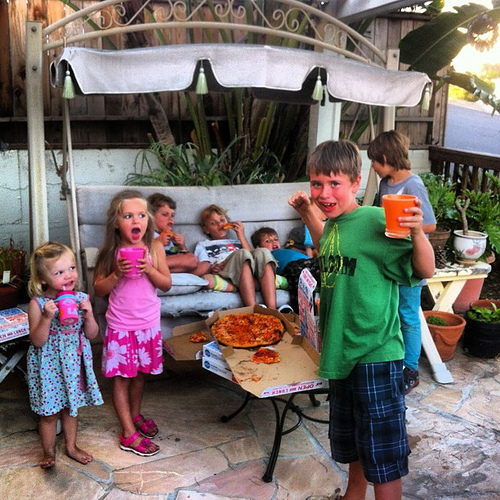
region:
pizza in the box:
[198, 299, 305, 370]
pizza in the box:
[212, 301, 331, 385]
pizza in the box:
[218, 279, 305, 365]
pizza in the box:
[198, 312, 340, 384]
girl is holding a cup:
[94, 180, 189, 395]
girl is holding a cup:
[19, 227, 90, 366]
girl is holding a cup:
[109, 195, 194, 334]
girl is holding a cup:
[19, 233, 131, 405]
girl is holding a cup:
[84, 155, 199, 322]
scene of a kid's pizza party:
[0, 3, 485, 483]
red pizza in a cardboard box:
[202, 308, 326, 402]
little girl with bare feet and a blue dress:
[20, 238, 100, 473]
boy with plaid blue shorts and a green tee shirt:
[283, 135, 439, 494]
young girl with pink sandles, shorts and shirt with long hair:
[89, 187, 174, 457]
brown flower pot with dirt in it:
[417, 306, 466, 361]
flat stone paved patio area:
[1, 355, 485, 492]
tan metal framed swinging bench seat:
[17, 0, 459, 399]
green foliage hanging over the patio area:
[395, 0, 490, 122]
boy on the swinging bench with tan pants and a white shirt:
[190, 204, 297, 319]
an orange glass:
[382, 192, 419, 239]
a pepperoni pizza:
[212, 311, 284, 348]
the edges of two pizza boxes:
[200, 340, 237, 385]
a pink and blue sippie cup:
[49, 289, 83, 322]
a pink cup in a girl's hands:
[120, 245, 146, 277]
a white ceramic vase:
[455, 226, 485, 259]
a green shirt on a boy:
[317, 207, 424, 379]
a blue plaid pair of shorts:
[327, 354, 412, 483]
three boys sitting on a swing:
[147, 191, 313, 308]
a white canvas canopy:
[57, 43, 434, 110]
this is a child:
[20, 242, 101, 477]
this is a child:
[92, 165, 178, 472]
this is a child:
[150, 186, 206, 308]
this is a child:
[179, 195, 290, 342]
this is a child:
[249, 223, 319, 335]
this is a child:
[277, 141, 424, 493]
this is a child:
[364, 127, 456, 426]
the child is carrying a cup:
[45, 289, 94, 331]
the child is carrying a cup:
[106, 235, 167, 290]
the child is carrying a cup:
[364, 180, 436, 255]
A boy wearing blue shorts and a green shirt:
[287, 135, 434, 497]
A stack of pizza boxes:
[195, 311, 325, 398]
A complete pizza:
[208, 311, 287, 346]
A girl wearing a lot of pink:
[93, 186, 171, 456]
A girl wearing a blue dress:
[20, 245, 104, 470]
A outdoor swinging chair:
[17, 14, 453, 390]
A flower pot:
[422, 310, 466, 362]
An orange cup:
[377, 191, 419, 239]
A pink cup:
[115, 243, 147, 279]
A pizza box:
[0, 305, 32, 343]